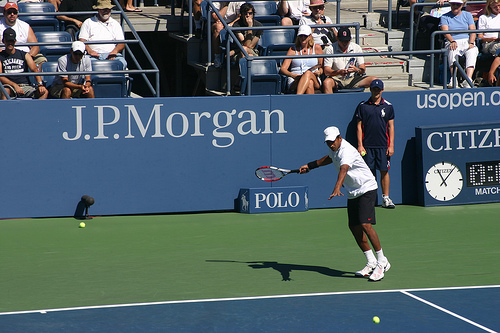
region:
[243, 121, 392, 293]
Man playing tennis on court.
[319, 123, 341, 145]
Man wearing white cap.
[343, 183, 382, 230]
Man wearing navy blue shorts.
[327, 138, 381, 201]
Man dressed in white shirt.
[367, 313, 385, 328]
Yellow tennis ball in air.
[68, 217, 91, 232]
Yellow tennis ball lying on ground.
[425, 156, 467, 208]
Clock on sign in background.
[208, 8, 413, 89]
Tennis fans in bleachers.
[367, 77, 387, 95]
Man in background wearing navy blue cap.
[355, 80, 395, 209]
Man standing ready to gather ball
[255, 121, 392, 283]
Tennis player about to deliver hit to ball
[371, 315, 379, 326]
Tennis ball in motion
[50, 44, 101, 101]
Spectator wearing hat in stands of game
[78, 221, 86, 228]
Tennis ball motionless on the ground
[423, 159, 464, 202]
Large analog clock giving time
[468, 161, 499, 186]
Section of digital clock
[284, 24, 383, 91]
A couple being spectators at match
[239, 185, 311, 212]
Sign of sponsors bordering arena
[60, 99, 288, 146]
A sponsor of the event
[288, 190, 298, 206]
white letter on blue wall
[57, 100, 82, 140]
white letter on blue wall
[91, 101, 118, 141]
white letter on blue wall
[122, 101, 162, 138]
white letter on blue wall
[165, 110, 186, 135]
white letter on blue wall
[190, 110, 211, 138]
white letter on blue wall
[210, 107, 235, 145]
white letter on blue wall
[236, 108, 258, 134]
white letter on blue wall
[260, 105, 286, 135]
white letter on blue wall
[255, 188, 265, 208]
white letter on blue wall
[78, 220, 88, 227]
A tennis ball on the ground.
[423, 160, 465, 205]
A clock on the wall.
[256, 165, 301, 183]
A tennis racket in someones hand.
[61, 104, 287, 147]
The name of a famous person.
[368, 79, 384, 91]
A mans blue hat.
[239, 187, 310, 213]
The brand name polo on a wall.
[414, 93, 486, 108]
The word usopen on the wall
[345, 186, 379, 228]
A pair of tennis shorts on a man.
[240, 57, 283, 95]
A fan seat in the stadium.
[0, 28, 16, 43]
A mans black hat.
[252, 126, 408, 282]
guy playing tennis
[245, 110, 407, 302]
guy wearing a white hat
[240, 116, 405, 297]
guy wearing a white shirt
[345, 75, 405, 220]
guy standing still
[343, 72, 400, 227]
guy wearing a navy blue hat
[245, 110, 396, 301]
guy wearing white tennis shoes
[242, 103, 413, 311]
guy wearing white socks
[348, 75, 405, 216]
guy wearing blue shorts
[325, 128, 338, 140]
the ball cap is white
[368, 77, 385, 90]
the hat is blue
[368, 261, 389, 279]
the shoe is white and black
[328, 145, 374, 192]
the shirt is white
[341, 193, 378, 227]
the shorts are black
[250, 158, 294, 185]
the tennis racquet is red, white and black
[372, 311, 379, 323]
a yellow tennis ball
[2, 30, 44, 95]
a person is sitting down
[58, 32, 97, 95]
a person is sitting down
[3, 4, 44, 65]
a person is sitting down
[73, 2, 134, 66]
a person is sitting down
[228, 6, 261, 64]
a person is sitting down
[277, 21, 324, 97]
a person is sitting down